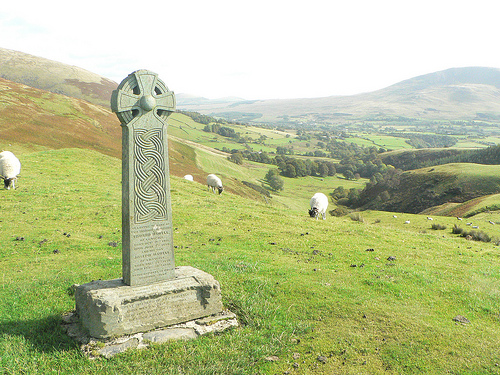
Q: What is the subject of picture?
A: Celtic cross.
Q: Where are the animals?
A: On grass.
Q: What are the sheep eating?
A: Grass.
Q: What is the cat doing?
A: No cat.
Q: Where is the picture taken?
A: A grave site.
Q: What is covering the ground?
A: Grass.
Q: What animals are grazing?
A: Sheep.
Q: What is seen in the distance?
A: Hills.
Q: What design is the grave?
A: Celtic.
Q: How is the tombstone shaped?
A: As a cross.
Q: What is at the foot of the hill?
A: Trees.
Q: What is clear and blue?
A: Sky.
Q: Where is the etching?
A: On the stone.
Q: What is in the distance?
A: Hills.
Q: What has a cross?
A: Epitaph.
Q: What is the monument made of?
A: Stone.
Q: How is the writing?
A: Etched.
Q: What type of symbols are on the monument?
A: Celtic.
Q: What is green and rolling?
A: Hills.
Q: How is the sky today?
A: Cloudy.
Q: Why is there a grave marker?
A: Someone died.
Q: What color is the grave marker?
A: Grey.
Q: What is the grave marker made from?
A: Stone.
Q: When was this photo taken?
A: Daytime.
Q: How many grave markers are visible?
A: One.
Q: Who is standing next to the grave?
A: No one.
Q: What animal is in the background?
A: Sheep.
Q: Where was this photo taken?
A: In the hills.